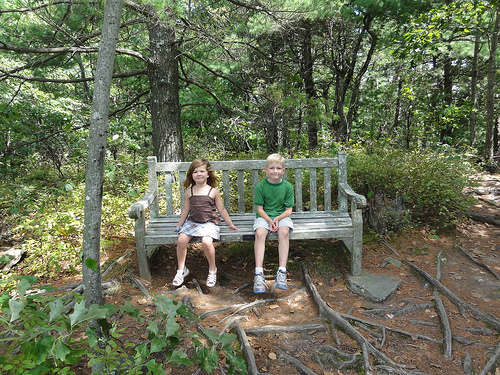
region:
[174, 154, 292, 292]
two kids sitting on a bench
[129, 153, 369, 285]
a wooden gray bench in a wood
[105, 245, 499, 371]
gray tree roots on the ground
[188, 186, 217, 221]
girl wearing a brown tank top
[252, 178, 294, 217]
boy wearing a green T-shirt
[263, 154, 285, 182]
a boy with blond hair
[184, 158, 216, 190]
a girl with light brown hair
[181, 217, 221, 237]
girl wearing a short skirt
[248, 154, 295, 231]
boy sitting with his hands clasped together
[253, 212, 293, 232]
boy wearing shorts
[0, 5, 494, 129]
forest of trees in background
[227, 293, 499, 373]
tree roots showing above ground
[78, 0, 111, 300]
tall, thin tree trunk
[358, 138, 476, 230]
bushes low to the ground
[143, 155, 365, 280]
bench with children sitting down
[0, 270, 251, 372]
bush of leaves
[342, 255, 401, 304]
rock slab under neath leg of bench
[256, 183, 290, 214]
green tee shirt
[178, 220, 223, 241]
khaki skirt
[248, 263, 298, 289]
tennis shoes with socks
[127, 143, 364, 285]
the kids on the bench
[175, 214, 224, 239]
the skirt on the girl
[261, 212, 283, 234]
the hands in the boys lap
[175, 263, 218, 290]
the sandals on the girl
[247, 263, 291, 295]
the shoes on the boys feet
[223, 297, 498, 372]
the tree vines growing in the ground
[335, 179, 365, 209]
the arm of the bench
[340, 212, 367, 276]
the leg of the bench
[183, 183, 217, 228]
the brown tank top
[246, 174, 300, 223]
the green tee shirt on the boy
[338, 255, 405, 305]
a large piece of rock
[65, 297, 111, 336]
a broad green leaf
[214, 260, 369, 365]
some large tree roots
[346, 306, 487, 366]
a bed of pine needles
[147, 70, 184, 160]
a thick tree trunk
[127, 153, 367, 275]
a worn wooden bench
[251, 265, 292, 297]
a pair of blue shoes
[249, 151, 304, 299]
a boy sitting on a bench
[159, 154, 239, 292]
a little girl in a skirt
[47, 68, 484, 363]
a bench in the forest